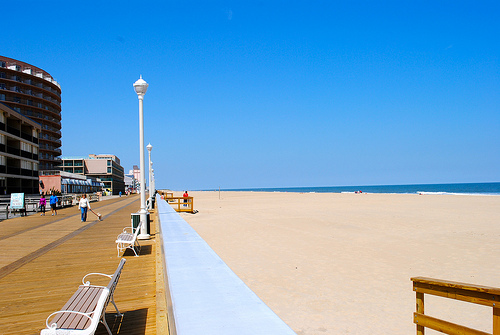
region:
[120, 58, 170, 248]
a long white poll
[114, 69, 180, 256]
a long poll with light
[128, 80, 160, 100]
a white light of poll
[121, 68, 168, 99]
a top of the poll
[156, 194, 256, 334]
a line board of the wall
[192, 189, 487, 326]
a clear view of sand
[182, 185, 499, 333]
a clean and neat sand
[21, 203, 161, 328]
a beautiful clean road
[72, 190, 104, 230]
a women walking road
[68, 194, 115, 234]
a woman walking with dog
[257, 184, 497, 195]
part of a body of ocean water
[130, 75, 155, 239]
a tall white lamp post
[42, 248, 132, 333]
part of a white bench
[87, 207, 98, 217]
a dog's leash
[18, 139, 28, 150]
a window of a building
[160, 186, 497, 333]
a large area of brown sand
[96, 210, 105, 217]
a small dog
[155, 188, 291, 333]
a long retaining wall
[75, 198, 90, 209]
a woman's white shirt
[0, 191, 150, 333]
part of a boardwalk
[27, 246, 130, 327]
White bench on walkway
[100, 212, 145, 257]
White bench on walkway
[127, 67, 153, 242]
Tall white light post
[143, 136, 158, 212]
Tall white light post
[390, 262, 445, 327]
Brown wooden deck in sand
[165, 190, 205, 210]
Brown wooden deck in sand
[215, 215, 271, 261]
Small part of brown sand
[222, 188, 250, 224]
Small part of brown sand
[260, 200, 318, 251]
Small part of brown sand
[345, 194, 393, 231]
Small part of brown sand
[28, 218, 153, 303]
wood deck is near beach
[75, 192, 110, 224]
person is walking dog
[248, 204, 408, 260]
sand is golden brown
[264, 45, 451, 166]
sky is clear and blue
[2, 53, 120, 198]
hotels are near the beach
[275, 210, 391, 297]
sand is near the water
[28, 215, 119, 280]
deck is golden brown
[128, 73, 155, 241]
lamppost is near the sand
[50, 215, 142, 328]
benches are on the deck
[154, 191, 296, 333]
sidewalk between deck and beach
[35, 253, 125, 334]
a bench on a boardwalk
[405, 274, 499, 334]
a handrail at a boardwalk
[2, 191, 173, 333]
a boardwalk next to the beach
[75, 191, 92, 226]
a woman walking a dog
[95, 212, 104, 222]
a dog walking on the boardwalk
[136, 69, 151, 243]
a light pole on the boardwalk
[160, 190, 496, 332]
tan sand next to the ocean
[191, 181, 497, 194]
blue ocean water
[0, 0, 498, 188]
a beautiful clear blue sky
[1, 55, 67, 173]
a hotel next to the boardwalk